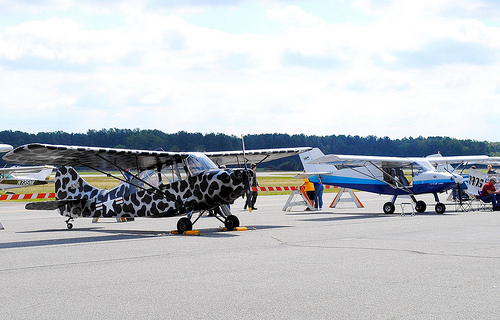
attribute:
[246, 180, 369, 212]
barricade — orange, white, striped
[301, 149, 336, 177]
tail — white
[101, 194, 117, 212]
star — white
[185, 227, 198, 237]
chocks — yellow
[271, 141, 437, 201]
plane — blue, white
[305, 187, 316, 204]
shorts — black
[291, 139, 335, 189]
tail — white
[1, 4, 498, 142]
clouds — white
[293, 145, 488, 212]
airplane — white, blue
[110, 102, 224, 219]
airplane — white, black, small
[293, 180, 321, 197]
shirt — yellow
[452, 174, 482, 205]
shirt — red